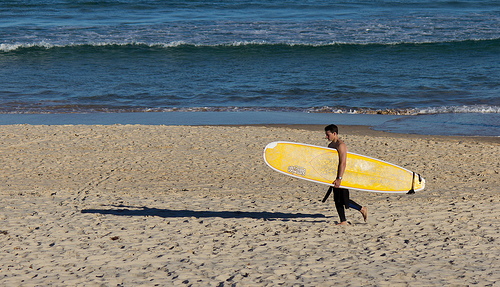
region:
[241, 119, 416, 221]
man walking on beach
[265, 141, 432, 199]
surfboard in man's arms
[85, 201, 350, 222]
shadow of man on beach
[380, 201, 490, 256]
footprints on sandy beach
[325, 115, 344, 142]
dark hair of surfer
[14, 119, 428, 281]
sandy beach in foreground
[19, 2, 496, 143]
body of water near sand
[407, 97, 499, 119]
waves crashing in on sand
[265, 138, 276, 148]
white spots on yellow board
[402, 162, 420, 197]
black strap on board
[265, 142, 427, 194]
yellow board with silver trim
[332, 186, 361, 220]
black pants of surfer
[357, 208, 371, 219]
foot of surfer at beach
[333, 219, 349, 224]
foot of surfer at beach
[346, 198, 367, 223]
raised leg of surfer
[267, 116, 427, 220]
surfer walking on beach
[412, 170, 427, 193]
tail of board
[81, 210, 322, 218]
shadow of surfer on beach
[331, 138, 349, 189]
arm of surfer over board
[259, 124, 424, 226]
surfer carrying yellow board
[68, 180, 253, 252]
the shadow is on the beach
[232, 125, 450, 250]
the man is walking on the beach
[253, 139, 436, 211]
the surfboard is big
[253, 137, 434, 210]
the surfboard is yellow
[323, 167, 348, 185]
the man is wearing a watch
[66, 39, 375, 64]
the wave is small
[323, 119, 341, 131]
the mans hair is dark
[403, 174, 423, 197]
the surfboard has a black leash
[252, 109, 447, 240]
the man is carrying a surfboard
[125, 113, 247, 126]
the beach is wet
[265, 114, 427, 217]
man is holding a surfboard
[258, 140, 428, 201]
the surfboard is yellow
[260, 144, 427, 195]
surfboard covering man's stomach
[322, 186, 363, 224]
man wearing wet suit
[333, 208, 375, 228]
the man is bare foot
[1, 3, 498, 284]
man is out on beach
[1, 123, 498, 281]
foot prints in the sand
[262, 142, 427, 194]
white spots on surfboard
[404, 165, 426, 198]
black strap on surfboard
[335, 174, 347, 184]
man wearing a watch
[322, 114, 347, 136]
face of the man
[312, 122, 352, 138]
face of the person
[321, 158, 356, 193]
hand of the person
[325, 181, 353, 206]
legs of the person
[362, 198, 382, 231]
feet of the person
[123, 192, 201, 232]
shadow on the sand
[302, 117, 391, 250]
a man holding board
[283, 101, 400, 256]
a man walking in sand